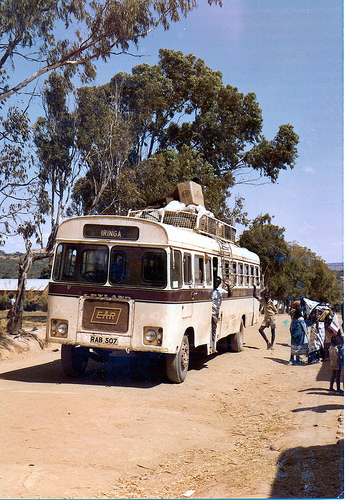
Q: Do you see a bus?
A: Yes, there is a bus.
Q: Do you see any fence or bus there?
A: Yes, there is a bus.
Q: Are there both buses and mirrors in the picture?
A: No, there is a bus but no mirrors.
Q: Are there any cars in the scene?
A: No, there are no cars.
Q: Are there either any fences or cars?
A: No, there are no cars or fences.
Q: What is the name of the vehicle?
A: The vehicle is a bus.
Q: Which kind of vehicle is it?
A: The vehicle is a bus.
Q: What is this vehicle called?
A: This is a bus.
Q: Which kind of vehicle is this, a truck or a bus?
A: This is a bus.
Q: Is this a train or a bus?
A: This is a bus.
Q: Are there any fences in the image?
A: No, there are no fences.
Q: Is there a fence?
A: No, there are no fences.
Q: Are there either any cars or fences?
A: No, there are no fences or cars.